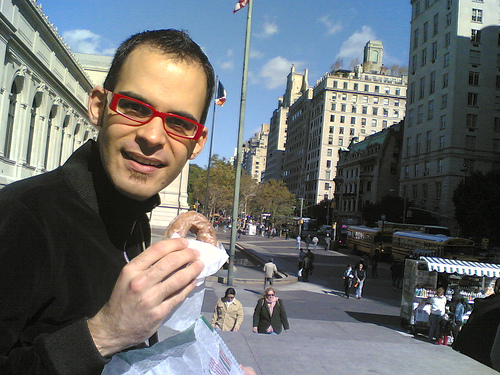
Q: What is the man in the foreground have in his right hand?
A: A donut.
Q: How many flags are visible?
A: Two.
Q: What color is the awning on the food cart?
A: Blue and white.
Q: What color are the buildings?
A: Light grey.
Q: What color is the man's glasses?
A: Red.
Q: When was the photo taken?
A: During the day.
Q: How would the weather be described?
A: Sunny with a few clouds.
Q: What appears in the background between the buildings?
A: A group of trees.